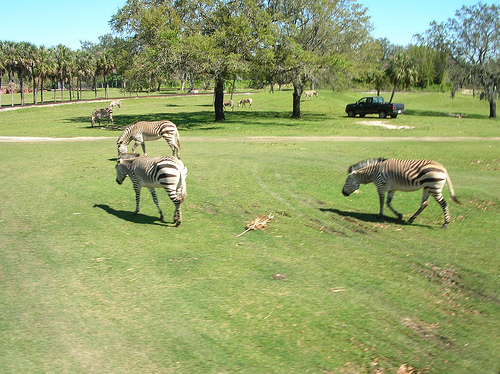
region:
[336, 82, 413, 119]
a blue truck on green grass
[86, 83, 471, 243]
zebras on a green field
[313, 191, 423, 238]
shadow cast on green field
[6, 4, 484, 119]
trees on a green field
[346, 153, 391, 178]
mane of zebra is long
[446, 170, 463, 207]
tail is long and has turf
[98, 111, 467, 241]
zebras face the left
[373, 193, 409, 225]
front legs of zebra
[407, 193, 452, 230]
back legs of zebra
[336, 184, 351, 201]
muzzle of the zebra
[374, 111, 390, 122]
large wheel on truck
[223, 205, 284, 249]
large gold leaf on the ground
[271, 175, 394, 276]
tracks on the green grass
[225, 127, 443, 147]
long path on the grass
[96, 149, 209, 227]
zebra walking on the grass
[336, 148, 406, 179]
large comb on zebra's head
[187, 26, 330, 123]
large green shade trees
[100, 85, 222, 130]
shadow cast under the trees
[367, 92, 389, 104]
windows at back of truck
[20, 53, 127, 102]
large selection of palm trees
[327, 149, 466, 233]
A zebra walking along.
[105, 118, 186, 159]
A zebra grazing in the field.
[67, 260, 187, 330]
Very short pale green grass.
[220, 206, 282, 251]
Large brown leaf on the ground.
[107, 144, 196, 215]
Zebra looking at the grass.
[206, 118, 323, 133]
Lush green grass across the path.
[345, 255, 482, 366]
Tire marks in the grass.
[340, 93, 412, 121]
Truck parked across the path.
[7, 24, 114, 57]
Bright blue sky above the tree tops.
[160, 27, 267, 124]
Bright leaves on the tree.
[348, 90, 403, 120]
The truck parked under the tree.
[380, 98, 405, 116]
The back part of the truck.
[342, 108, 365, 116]
The front wheels of the truck.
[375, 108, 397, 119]
The back wheels of the truck.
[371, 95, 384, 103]
The back window of the truck.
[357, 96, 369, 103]
The driver side window of the truck.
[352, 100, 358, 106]
The side view mirror on the truck.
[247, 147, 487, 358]
The tire tracks on the grass.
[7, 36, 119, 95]
The palm trees on the right.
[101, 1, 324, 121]
The two trees in front of the pickup truck.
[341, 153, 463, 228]
Black and white zebra to the right.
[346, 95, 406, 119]
Dark pickup truck.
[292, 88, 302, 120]
Brown tree trunk in front of a truck.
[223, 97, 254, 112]
Two zebras between two middle trees.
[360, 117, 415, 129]
Dirt ground patch beside the truck.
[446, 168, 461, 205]
A black and white zebra tail on the right side zebra.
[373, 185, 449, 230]
Four legs of a black and white zebra to the right.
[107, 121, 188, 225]
Two black and white zebras on the close left.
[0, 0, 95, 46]
Blue sky above the left trees.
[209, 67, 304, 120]
Two brown tree trunks in the middle.